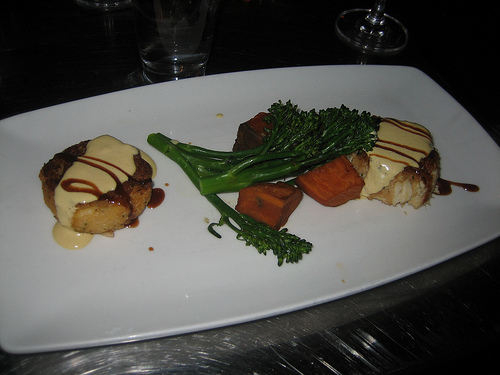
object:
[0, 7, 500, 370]
table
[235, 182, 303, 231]
potato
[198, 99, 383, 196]
broccoli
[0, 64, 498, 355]
plate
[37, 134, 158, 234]
food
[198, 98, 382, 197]
vegetable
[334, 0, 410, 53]
glass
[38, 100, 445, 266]
dinner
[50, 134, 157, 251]
sauce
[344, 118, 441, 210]
meat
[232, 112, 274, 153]
potato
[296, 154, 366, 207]
potato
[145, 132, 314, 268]
broccoli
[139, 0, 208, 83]
glass